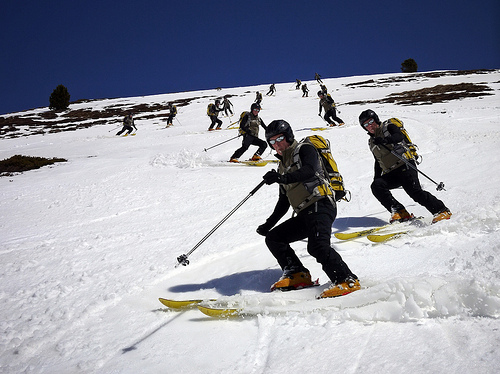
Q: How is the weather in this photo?
A: It is clear.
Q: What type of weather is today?
A: It is clear.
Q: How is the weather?
A: It is clear.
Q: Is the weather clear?
A: Yes, it is clear.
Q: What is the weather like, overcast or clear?
A: It is clear.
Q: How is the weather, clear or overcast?
A: It is clear.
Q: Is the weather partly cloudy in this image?
A: No, it is clear.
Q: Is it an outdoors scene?
A: Yes, it is outdoors.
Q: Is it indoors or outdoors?
A: It is outdoors.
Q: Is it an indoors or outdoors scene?
A: It is outdoors.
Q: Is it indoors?
A: No, it is outdoors.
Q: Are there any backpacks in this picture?
A: Yes, there is a backpack.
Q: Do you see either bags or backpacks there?
A: Yes, there is a backpack.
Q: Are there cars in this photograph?
A: No, there are no cars.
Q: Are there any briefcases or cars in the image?
A: No, there are no cars or briefcases.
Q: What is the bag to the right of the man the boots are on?
A: The bag is a backpack.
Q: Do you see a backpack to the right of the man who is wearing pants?
A: Yes, there is a backpack to the right of the man.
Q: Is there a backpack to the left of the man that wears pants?
A: No, the backpack is to the right of the man.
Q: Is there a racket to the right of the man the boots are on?
A: No, there is a backpack to the right of the man.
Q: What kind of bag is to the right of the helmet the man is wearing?
A: The bag is a backpack.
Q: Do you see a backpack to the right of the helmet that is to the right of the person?
A: Yes, there is a backpack to the right of the helmet.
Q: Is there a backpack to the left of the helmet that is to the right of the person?
A: No, the backpack is to the right of the helmet.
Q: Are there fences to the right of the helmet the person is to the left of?
A: No, there is a backpack to the right of the helmet.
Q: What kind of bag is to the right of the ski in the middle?
A: The bag is a backpack.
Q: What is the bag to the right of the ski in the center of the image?
A: The bag is a backpack.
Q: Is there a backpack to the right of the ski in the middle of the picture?
A: Yes, there is a backpack to the right of the ski.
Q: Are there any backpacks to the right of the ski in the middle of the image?
A: Yes, there is a backpack to the right of the ski.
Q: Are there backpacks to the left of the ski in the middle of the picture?
A: No, the backpack is to the right of the ski.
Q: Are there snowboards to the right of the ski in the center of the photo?
A: No, there is a backpack to the right of the ski.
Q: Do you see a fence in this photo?
A: No, there are no fences.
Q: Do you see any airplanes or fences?
A: No, there are no fences or airplanes.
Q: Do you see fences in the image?
A: No, there are no fences.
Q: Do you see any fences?
A: No, there are no fences.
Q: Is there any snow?
A: Yes, there is snow.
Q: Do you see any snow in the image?
A: Yes, there is snow.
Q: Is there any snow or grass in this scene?
A: Yes, there is snow.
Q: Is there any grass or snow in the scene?
A: Yes, there is snow.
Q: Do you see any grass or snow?
A: Yes, there is snow.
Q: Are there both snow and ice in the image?
A: No, there is snow but no ice.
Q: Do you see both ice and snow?
A: No, there is snow but no ice.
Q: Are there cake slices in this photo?
A: No, there are no cake slices.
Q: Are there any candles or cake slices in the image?
A: No, there are no cake slices or candles.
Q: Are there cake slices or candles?
A: No, there are no cake slices or candles.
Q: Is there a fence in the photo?
A: No, there are no fences.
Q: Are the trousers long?
A: Yes, the trousers are long.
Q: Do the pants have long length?
A: Yes, the pants are long.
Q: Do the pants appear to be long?
A: Yes, the pants are long.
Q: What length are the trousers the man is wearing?
A: The pants are long.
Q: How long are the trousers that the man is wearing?
A: The trousers are long.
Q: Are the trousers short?
A: No, the trousers are long.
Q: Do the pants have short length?
A: No, the pants are long.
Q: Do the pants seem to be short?
A: No, the pants are long.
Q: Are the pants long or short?
A: The pants are long.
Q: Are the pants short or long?
A: The pants are long.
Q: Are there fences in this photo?
A: No, there are no fences.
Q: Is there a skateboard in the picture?
A: No, there are no skateboards.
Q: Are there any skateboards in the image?
A: No, there are no skateboards.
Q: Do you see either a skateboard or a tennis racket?
A: No, there are no skateboards or rackets.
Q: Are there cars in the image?
A: No, there are no cars.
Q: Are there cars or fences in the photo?
A: No, there are no cars or fences.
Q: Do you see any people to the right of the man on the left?
A: Yes, there is a person to the right of the man.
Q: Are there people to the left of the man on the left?
A: No, the person is to the right of the man.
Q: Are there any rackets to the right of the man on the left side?
A: No, there is a person to the right of the man.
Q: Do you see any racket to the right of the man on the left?
A: No, there is a person to the right of the man.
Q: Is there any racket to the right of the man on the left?
A: No, there is a person to the right of the man.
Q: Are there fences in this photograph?
A: No, there are no fences.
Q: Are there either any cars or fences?
A: No, there are no fences or cars.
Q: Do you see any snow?
A: Yes, there is snow.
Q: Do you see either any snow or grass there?
A: Yes, there is snow.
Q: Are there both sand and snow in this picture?
A: No, there is snow but no sand.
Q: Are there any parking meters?
A: No, there are no parking meters.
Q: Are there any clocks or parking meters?
A: No, there are no parking meters or clocks.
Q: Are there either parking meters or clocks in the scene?
A: No, there are no parking meters or clocks.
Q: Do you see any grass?
A: Yes, there is grass.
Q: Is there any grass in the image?
A: Yes, there is grass.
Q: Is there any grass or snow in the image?
A: Yes, there is grass.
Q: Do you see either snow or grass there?
A: Yes, there is grass.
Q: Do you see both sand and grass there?
A: No, there is grass but no sand.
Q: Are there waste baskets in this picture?
A: No, there are no waste baskets.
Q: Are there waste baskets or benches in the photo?
A: No, there are no waste baskets or benches.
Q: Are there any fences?
A: No, there are no fences.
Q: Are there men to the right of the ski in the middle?
A: Yes, there is a man to the right of the ski.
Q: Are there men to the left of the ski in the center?
A: No, the man is to the right of the ski.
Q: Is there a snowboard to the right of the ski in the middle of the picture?
A: No, there is a man to the right of the ski.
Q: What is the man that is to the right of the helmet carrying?
A: The man is carrying a backpack.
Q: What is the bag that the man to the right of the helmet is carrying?
A: The bag is a backpack.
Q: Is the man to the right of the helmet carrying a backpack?
A: Yes, the man is carrying a backpack.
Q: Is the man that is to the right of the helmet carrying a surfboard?
A: No, the man is carrying a backpack.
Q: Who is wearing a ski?
A: The man is wearing a ski.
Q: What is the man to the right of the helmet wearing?
A: The man is wearing a ski.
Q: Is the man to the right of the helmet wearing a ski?
A: Yes, the man is wearing a ski.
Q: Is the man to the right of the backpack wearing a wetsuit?
A: No, the man is wearing a ski.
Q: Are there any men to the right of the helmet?
A: Yes, there is a man to the right of the helmet.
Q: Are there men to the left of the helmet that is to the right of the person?
A: No, the man is to the right of the helmet.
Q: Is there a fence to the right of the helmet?
A: No, there is a man to the right of the helmet.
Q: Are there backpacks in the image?
A: Yes, there is a backpack.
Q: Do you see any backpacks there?
A: Yes, there is a backpack.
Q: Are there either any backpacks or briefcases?
A: Yes, there is a backpack.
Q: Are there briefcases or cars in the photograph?
A: No, there are no cars or briefcases.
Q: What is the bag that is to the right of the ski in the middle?
A: The bag is a backpack.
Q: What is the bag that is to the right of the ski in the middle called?
A: The bag is a backpack.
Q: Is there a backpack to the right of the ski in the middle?
A: Yes, there is a backpack to the right of the ski.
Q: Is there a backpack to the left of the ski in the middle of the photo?
A: No, the backpack is to the right of the ski.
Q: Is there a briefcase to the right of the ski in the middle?
A: No, there is a backpack to the right of the ski.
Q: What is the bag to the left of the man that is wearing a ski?
A: The bag is a backpack.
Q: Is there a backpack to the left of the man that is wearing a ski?
A: Yes, there is a backpack to the left of the man.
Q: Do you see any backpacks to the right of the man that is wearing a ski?
A: No, the backpack is to the left of the man.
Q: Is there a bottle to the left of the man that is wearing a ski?
A: No, there is a backpack to the left of the man.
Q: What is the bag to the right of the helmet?
A: The bag is a backpack.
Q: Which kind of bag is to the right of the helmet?
A: The bag is a backpack.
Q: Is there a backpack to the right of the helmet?
A: Yes, there is a backpack to the right of the helmet.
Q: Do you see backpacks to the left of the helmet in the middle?
A: No, the backpack is to the right of the helmet.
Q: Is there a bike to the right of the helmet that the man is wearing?
A: No, there is a backpack to the right of the helmet.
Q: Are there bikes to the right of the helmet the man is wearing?
A: No, there is a backpack to the right of the helmet.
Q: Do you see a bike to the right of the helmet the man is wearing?
A: No, there is a backpack to the right of the helmet.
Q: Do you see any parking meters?
A: No, there are no parking meters.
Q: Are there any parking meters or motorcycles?
A: No, there are no parking meters or motorcycles.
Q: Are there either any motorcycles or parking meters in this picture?
A: No, there are no parking meters or motorcycles.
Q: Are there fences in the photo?
A: No, there are no fences.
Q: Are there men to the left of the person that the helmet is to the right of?
A: Yes, there is a man to the left of the person.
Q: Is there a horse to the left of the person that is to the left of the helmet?
A: No, there is a man to the left of the person.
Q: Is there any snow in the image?
A: Yes, there is snow.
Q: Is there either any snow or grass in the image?
A: Yes, there is snow.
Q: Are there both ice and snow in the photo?
A: No, there is snow but no ice.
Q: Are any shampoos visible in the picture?
A: No, there are no shampoos.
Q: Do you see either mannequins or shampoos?
A: No, there are no shampoos or mannequins.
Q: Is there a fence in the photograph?
A: No, there are no fences.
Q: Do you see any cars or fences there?
A: No, there are no fences or cars.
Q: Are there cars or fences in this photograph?
A: No, there are no fences or cars.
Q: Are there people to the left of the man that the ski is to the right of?
A: Yes, there is a person to the left of the man.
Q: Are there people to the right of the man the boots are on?
A: No, the person is to the left of the man.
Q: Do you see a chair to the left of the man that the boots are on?
A: No, there is a person to the left of the man.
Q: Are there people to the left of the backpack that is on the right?
A: Yes, there is a person to the left of the backpack.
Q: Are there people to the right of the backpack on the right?
A: No, the person is to the left of the backpack.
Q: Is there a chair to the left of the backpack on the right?
A: No, there is a person to the left of the backpack.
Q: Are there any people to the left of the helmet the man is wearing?
A: Yes, there is a person to the left of the helmet.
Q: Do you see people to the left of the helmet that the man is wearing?
A: Yes, there is a person to the left of the helmet.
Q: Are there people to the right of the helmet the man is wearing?
A: No, the person is to the left of the helmet.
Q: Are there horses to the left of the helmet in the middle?
A: No, there is a person to the left of the helmet.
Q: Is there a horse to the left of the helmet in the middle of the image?
A: No, there is a person to the left of the helmet.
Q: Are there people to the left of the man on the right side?
A: Yes, there is a person to the left of the man.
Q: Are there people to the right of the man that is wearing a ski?
A: No, the person is to the left of the man.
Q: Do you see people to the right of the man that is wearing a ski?
A: No, the person is to the left of the man.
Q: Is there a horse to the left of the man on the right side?
A: No, there is a person to the left of the man.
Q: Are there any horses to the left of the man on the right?
A: No, there is a person to the left of the man.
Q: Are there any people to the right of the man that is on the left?
A: Yes, there is a person to the right of the man.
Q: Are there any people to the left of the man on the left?
A: No, the person is to the right of the man.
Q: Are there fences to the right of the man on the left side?
A: No, there is a person to the right of the man.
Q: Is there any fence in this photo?
A: No, there are no fences.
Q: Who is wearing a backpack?
A: The man is wearing a backpack.